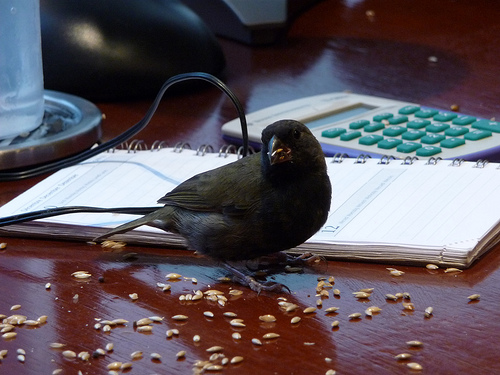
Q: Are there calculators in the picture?
A: Yes, there is a calculator.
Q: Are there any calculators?
A: Yes, there is a calculator.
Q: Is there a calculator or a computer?
A: Yes, there is a calculator.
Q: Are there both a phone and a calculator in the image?
A: Yes, there are both a calculator and a phone.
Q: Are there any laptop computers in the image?
A: No, there are no laptop computers.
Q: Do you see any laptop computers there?
A: No, there are no laptop computers.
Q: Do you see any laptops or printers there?
A: No, there are no laptops or printers.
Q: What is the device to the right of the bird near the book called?
A: The device is a calculator.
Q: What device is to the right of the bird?
A: The device is a calculator.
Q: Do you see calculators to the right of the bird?
A: Yes, there is a calculator to the right of the bird.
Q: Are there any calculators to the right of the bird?
A: Yes, there is a calculator to the right of the bird.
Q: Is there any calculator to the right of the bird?
A: Yes, there is a calculator to the right of the bird.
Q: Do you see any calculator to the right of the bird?
A: Yes, there is a calculator to the right of the bird.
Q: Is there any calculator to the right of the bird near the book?
A: Yes, there is a calculator to the right of the bird.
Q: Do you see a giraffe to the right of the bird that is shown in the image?
A: No, there is a calculator to the right of the bird.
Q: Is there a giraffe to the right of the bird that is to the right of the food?
A: No, there is a calculator to the right of the bird.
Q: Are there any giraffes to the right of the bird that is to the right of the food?
A: No, there is a calculator to the right of the bird.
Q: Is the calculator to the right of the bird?
A: Yes, the calculator is to the right of the bird.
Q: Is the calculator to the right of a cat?
A: No, the calculator is to the right of the bird.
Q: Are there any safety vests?
A: No, there are no safety vests.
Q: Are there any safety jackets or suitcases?
A: No, there are no safety jackets or suitcases.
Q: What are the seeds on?
A: The seeds are on the desk.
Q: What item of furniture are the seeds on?
A: The seeds are on the desk.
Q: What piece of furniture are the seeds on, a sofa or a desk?
A: The seeds are on a desk.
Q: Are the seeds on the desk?
A: Yes, the seeds are on the desk.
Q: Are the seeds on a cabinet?
A: No, the seeds are on the desk.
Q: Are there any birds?
A: Yes, there is a bird.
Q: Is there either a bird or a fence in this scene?
A: Yes, there is a bird.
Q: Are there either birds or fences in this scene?
A: Yes, there is a bird.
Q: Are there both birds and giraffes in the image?
A: No, there is a bird but no giraffes.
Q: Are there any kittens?
A: No, there are no kittens.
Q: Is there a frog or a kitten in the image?
A: No, there are no kittens or frogs.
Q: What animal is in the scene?
A: The animal is a bird.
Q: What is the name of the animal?
A: The animal is a bird.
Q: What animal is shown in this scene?
A: The animal is a bird.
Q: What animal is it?
A: The animal is a bird.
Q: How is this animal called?
A: This is a bird.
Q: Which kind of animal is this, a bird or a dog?
A: This is a bird.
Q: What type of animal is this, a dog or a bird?
A: This is a bird.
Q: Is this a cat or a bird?
A: This is a bird.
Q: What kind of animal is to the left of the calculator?
A: The animal is a bird.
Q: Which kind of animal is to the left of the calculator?
A: The animal is a bird.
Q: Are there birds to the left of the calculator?
A: Yes, there is a bird to the left of the calculator.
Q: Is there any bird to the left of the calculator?
A: Yes, there is a bird to the left of the calculator.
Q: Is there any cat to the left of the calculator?
A: No, there is a bird to the left of the calculator.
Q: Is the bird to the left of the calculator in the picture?
A: Yes, the bird is to the left of the calculator.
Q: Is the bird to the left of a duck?
A: No, the bird is to the left of the calculator.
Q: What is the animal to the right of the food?
A: The animal is a bird.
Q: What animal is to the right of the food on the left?
A: The animal is a bird.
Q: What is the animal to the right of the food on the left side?
A: The animal is a bird.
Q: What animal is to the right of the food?
A: The animal is a bird.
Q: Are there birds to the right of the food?
A: Yes, there is a bird to the right of the food.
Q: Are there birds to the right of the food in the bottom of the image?
A: Yes, there is a bird to the right of the food.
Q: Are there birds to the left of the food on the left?
A: No, the bird is to the right of the food.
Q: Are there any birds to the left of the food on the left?
A: No, the bird is to the right of the food.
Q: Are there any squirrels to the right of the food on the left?
A: No, there is a bird to the right of the food.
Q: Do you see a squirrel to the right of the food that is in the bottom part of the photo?
A: No, there is a bird to the right of the food.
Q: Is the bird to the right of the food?
A: Yes, the bird is to the right of the food.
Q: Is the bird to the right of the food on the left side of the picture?
A: Yes, the bird is to the right of the food.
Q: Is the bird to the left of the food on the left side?
A: No, the bird is to the right of the food.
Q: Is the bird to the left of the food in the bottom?
A: No, the bird is to the right of the food.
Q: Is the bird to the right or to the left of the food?
A: The bird is to the right of the food.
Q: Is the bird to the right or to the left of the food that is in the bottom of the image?
A: The bird is to the right of the food.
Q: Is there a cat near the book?
A: No, there is a bird near the book.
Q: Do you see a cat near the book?
A: No, there is a bird near the book.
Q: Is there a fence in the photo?
A: No, there are no fences.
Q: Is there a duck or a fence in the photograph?
A: No, there are no fences or ducks.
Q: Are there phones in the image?
A: Yes, there is a phone.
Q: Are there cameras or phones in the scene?
A: Yes, there is a phone.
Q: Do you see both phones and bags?
A: No, there is a phone but no bags.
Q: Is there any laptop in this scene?
A: No, there are no laptops.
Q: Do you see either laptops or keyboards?
A: No, there are no laptops or keyboards.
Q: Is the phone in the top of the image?
A: Yes, the phone is in the top of the image.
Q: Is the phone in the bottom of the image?
A: No, the phone is in the top of the image.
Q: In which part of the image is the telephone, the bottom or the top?
A: The telephone is in the top of the image.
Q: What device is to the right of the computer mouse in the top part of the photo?
A: The device is a phone.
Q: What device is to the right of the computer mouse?
A: The device is a phone.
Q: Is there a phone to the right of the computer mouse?
A: Yes, there is a phone to the right of the computer mouse.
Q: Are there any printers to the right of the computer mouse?
A: No, there is a phone to the right of the computer mouse.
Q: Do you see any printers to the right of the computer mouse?
A: No, there is a phone to the right of the computer mouse.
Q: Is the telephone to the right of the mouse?
A: Yes, the telephone is to the right of the mouse.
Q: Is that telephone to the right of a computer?
A: No, the telephone is to the right of the mouse.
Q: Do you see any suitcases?
A: No, there are no suitcases.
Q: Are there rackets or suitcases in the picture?
A: No, there are no suitcases or rackets.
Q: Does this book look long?
A: Yes, the book is long.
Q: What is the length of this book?
A: The book is long.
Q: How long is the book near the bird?
A: The book is long.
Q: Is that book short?
A: No, the book is long.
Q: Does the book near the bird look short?
A: No, the book is long.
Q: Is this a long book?
A: Yes, this is a long book.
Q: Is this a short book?
A: No, this is a long book.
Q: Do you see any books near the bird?
A: Yes, there is a book near the bird.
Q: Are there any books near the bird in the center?
A: Yes, there is a book near the bird.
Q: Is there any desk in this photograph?
A: Yes, there is a desk.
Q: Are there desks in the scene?
A: Yes, there is a desk.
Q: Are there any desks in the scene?
A: Yes, there is a desk.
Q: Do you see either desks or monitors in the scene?
A: Yes, there is a desk.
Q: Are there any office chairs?
A: No, there are no office chairs.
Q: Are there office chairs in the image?
A: No, there are no office chairs.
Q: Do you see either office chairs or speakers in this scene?
A: No, there are no office chairs or speakers.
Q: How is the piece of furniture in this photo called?
A: The piece of furniture is a desk.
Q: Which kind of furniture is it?
A: The piece of furniture is a desk.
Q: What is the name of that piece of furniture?
A: That is a desk.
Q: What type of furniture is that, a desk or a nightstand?
A: That is a desk.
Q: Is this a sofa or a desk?
A: This is a desk.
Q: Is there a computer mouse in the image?
A: Yes, there is a computer mouse.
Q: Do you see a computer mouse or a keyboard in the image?
A: Yes, there is a computer mouse.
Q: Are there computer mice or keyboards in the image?
A: Yes, there is a computer mouse.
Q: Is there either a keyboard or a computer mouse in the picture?
A: Yes, there is a computer mouse.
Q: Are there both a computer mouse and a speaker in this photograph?
A: No, there is a computer mouse but no speakers.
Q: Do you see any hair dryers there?
A: No, there are no hair dryers.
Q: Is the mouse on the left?
A: Yes, the mouse is on the left of the image.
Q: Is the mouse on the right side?
A: No, the mouse is on the left of the image.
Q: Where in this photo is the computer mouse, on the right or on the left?
A: The computer mouse is on the left of the image.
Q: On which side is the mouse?
A: The mouse is on the left of the image.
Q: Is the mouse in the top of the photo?
A: Yes, the mouse is in the top of the image.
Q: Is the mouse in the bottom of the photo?
A: No, the mouse is in the top of the image.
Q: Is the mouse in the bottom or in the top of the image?
A: The mouse is in the top of the image.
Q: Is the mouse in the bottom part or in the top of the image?
A: The mouse is in the top of the image.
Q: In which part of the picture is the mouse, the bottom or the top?
A: The mouse is in the top of the image.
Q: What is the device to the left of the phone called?
A: The device is a computer mouse.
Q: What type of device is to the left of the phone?
A: The device is a computer mouse.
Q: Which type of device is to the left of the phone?
A: The device is a computer mouse.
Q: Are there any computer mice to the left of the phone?
A: Yes, there is a computer mouse to the left of the phone.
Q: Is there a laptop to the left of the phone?
A: No, there is a computer mouse to the left of the phone.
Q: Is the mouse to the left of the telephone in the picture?
A: Yes, the mouse is to the left of the telephone.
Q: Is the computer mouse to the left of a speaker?
A: No, the computer mouse is to the left of the telephone.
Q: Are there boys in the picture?
A: No, there are no boys.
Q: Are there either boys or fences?
A: No, there are no boys or fences.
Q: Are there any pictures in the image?
A: No, there are no pictures.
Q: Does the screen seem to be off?
A: Yes, the screen is off.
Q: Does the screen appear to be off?
A: Yes, the screen is off.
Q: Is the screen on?
A: No, the screen is off.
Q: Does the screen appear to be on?
A: No, the screen is off.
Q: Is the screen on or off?
A: The screen is off.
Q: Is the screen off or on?
A: The screen is off.